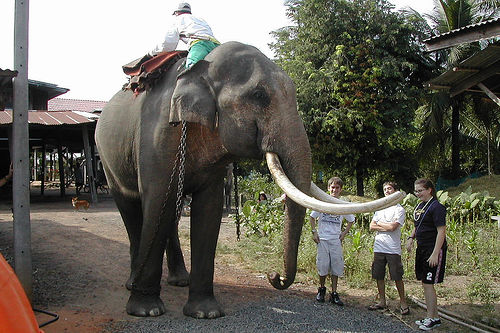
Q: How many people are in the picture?
A: Four.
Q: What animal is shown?
A: An elephant.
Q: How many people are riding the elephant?
A: One.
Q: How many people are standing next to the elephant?
A: Three.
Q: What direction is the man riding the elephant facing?
A: Backwards.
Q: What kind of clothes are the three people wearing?
A: Shorts and t shirts.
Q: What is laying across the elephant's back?
A: Heavy blankets.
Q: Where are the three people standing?
A: Next to the elephant.